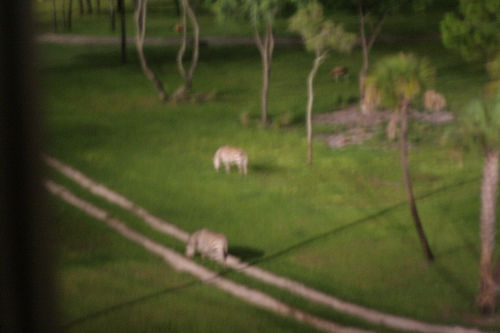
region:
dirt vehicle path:
[50, 143, 152, 256]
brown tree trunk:
[304, 56, 321, 171]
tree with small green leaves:
[289, 7, 361, 62]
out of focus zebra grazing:
[166, 211, 247, 279]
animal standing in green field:
[170, 128, 284, 205]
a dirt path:
[36, 30, 120, 51]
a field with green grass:
[104, 110, 195, 182]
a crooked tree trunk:
[126, 0, 212, 100]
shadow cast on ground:
[290, 177, 400, 272]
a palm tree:
[461, 93, 498, 305]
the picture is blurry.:
[3, 1, 493, 328]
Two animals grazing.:
[177, 133, 253, 267]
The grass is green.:
[32, 34, 489, 327]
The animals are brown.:
[176, 138, 252, 266]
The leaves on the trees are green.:
[207, 2, 499, 139]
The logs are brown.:
[30, 147, 450, 331]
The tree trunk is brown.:
[386, 98, 441, 265]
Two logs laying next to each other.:
[30, 132, 474, 330]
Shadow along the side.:
[1, 1, 48, 330]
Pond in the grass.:
[279, 66, 447, 162]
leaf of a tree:
[416, 73, 428, 82]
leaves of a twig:
[411, 73, 432, 87]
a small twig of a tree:
[394, 84, 411, 97]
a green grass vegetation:
[343, 259, 353, 274]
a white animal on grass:
[237, 156, 251, 160]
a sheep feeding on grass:
[198, 235, 225, 245]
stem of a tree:
[311, 67, 323, 117]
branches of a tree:
[396, 45, 407, 64]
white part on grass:
[235, 282, 245, 309]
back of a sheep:
[245, 158, 250, 160]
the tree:
[347, 80, 462, 287]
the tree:
[379, 80, 416, 324]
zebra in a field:
[200, 131, 275, 193]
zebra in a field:
[157, 221, 252, 271]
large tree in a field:
[283, 0, 352, 176]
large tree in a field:
[344, 46, 484, 283]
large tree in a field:
[213, 0, 288, 140]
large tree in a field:
[439, 103, 496, 313]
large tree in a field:
[433, 3, 498, 89]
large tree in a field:
[328, 1, 425, 121]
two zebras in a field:
[146, 125, 313, 309]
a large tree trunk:
[87, 0, 142, 67]